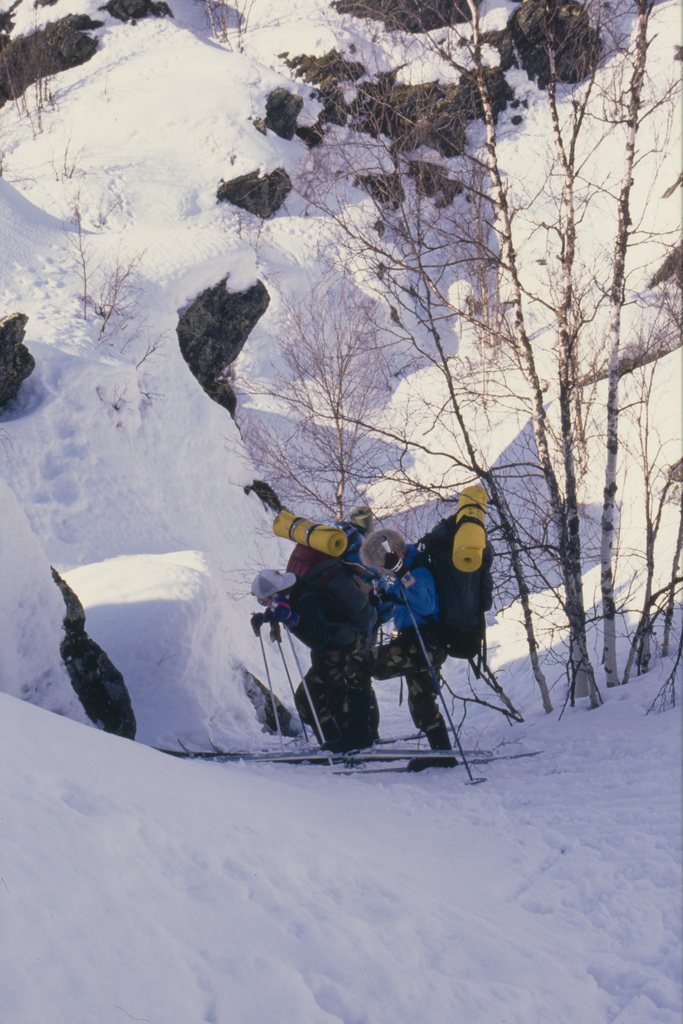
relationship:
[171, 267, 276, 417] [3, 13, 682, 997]
rock in snow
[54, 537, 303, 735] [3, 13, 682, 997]
rock in snow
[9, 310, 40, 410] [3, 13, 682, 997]
rock in snow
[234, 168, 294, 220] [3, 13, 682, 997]
rock in snow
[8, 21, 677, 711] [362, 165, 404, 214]
rock in snow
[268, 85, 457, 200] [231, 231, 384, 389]
rock in snow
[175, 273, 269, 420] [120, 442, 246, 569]
rock in snow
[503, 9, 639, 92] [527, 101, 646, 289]
rock in snow